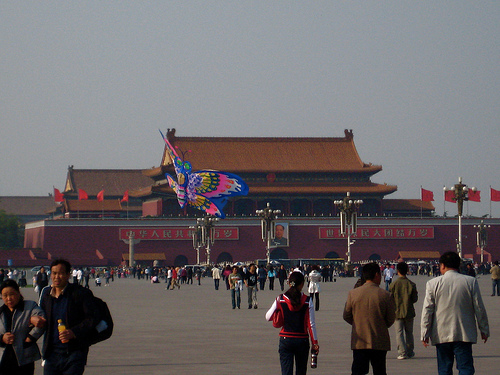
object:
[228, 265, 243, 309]
person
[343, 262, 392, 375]
person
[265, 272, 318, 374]
person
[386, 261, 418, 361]
person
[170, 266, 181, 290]
person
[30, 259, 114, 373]
man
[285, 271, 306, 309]
hair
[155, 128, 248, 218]
kite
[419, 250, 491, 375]
person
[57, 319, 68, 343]
bottle